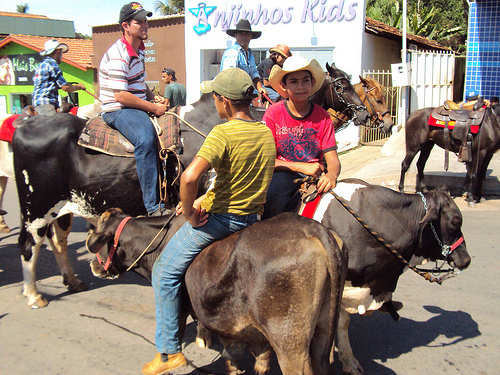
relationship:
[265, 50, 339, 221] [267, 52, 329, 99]
boy has a cowboy hat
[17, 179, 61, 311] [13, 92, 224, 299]
right leg of cow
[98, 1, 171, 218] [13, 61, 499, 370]
man on cows and horses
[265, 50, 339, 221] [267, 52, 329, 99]
boy has cowboy hat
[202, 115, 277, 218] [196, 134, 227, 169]
shirt has short sleeves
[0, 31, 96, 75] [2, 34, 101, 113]
roof of a building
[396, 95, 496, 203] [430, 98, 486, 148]
brown horse has a saddle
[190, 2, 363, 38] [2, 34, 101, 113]
business name on building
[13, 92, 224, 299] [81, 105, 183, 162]
cow has a harness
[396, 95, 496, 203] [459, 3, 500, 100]
horse by wall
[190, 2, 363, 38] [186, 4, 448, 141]
business name on building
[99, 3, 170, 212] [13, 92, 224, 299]
man on cow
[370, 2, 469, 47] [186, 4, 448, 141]
trees behind building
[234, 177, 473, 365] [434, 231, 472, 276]
cow has bridle